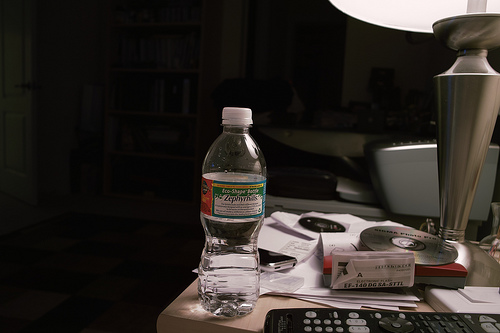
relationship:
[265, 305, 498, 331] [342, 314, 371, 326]
remote has button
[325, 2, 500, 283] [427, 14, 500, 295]
lamp has base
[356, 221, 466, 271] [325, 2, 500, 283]
compact disc by lamp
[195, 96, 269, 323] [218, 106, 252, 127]
bottle has cap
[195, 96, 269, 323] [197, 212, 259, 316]
bottle has liquid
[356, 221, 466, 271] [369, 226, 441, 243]
compact disc has writing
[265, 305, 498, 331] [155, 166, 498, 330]
remote on top of desk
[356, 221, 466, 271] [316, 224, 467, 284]
compact disc on top of paper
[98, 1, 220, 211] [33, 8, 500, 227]
shelves against wall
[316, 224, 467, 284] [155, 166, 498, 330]
paper on top of desk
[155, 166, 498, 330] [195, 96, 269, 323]
desk has bottle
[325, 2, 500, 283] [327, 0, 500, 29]
lamp has shade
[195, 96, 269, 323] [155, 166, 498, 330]
bottle on top of desk